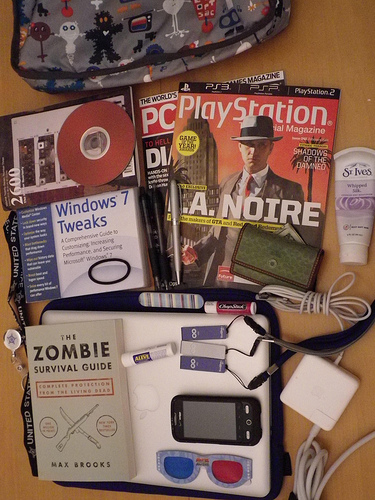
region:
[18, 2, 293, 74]
Gray bag with various cartoon figures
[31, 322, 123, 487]
"Zombie Survival Guide" book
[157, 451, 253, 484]
Red and blue 3-D glasses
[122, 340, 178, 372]
Travel bottle of Aleve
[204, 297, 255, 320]
Tube of Chap-Stick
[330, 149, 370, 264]
White tube of St. Ives lotion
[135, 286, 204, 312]
Nail file with multicolored stripes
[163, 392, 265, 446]
Black phone laying on Apple laptop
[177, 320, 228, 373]
Purple and gray memory sticks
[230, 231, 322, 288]
Green clutch with brown trim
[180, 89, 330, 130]
The word Playstation in white letters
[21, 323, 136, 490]
Zombie book on table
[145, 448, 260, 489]
3D glasses that are red and blue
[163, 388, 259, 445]
small black cell phone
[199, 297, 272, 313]
Cherry chap stick in a tube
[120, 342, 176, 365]
Tube of Aleve on table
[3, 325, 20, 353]
Lanyard with a charm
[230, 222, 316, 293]
Green leather wallet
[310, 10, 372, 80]
Wooden table that is brown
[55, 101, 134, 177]
Red round CD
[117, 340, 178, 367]
small white tube of pain medicine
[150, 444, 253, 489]
blue and red 3-D glasses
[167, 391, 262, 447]
black cell phone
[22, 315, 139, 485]
light brown paperback book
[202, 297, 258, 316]
red and white lip balm tube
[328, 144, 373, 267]
white tube of hand lotion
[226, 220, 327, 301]
small rectangular green and brown change purse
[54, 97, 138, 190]
plastic red CD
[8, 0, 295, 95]
gray bag on brown wooden table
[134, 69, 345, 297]
video game magazines on brown wooden table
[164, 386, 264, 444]
A black cell phone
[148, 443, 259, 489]
3D glasses in the foreground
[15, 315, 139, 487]
A gray colored book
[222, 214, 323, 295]
A green colored wallet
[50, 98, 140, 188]
A CD disc in the foreground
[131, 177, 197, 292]
Three pens in the foreground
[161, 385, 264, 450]
Cell phone is a smartphone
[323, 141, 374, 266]
Small bottle of lotion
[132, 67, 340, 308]
Two gaming magazines under pens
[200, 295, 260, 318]
Chapstick in the foreground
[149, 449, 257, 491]
Three D glasses on the apple pc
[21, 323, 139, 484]
Zombie Survival Guide on the apple pc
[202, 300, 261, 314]
Chapstick at the top of the pc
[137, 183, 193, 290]
Three ink pens on the magazines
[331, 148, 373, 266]
St. Ives hand cream beside the magazines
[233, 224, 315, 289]
Billfold laying on top of magazines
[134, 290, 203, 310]
Emery board at the end of the Apple pc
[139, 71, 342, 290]
Play Station magazines lying on the table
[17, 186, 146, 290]
Windows 7 tweaks CD box lying on the table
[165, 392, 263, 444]
Cellphone lying on the top of the Apple pc